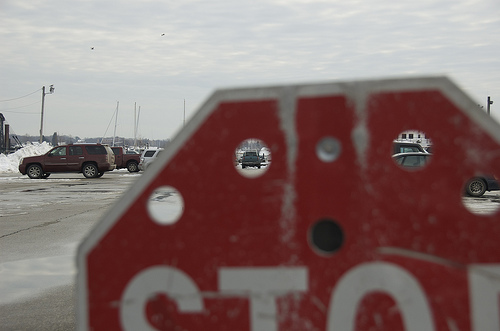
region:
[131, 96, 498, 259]
the stop sign has holes in it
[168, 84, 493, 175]
the stop sign is red & white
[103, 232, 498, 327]
the word stop is in white letters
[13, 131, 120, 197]
this vehicle is burgundy in color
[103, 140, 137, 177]
the truck next to it is burgundy as well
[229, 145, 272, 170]
one can see a vehicle thru the hole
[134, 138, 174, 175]
this vehicle is white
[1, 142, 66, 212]
snow is piled high in front of the cars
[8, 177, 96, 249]
the parking lot is melted off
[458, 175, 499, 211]
a wheel is visible thru the hole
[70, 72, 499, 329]
the sign is red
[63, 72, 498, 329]
the sign is a stop sign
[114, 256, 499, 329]
the sign has white writing on it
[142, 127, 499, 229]
the sign has holes in it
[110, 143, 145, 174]
the truck is dirty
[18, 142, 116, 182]
the suv is red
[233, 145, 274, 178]
the suv is blue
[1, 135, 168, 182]
the snow is on the ground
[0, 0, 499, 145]
the sky is cloudy and grey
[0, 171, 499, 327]
the pavement is wet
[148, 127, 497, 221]
four holes in the top of a stop sign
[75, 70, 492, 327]
old red stop sign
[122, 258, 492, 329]
lettering on the stop sign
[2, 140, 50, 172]
pile of snow in front of the trucks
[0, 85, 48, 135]
light pole and power line by the snow pile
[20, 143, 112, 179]
Red SUV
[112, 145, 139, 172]
red pick-up behind the SUV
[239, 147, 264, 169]
blue truck seen completely through stop sign hole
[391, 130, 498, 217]
two holes on the right in the stop sign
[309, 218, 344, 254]
black circle on stop sign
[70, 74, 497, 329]
The top of a red and white stop sign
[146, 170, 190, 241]
A whole on a sign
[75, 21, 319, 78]
A very overcast, cloudy sky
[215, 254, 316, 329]
The top of the letter T in white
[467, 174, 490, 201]
The back tire of a car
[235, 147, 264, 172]
The back view of a car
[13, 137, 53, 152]
A pile of white snow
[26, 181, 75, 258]
A wet slippery road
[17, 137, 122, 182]
The side of a red wagon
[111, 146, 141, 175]
The side part of a truck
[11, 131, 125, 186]
large red sport truck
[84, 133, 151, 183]
large red pickup truck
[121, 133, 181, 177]
small white sport truck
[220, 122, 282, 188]
truck through a bullet hole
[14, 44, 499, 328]
stop sign with bullet holes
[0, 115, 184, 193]
cars parked near snow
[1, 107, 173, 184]
cars parked in winter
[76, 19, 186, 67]
birds flying in the air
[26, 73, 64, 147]
tall wooden power pole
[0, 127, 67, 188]
large bank of plowed snow